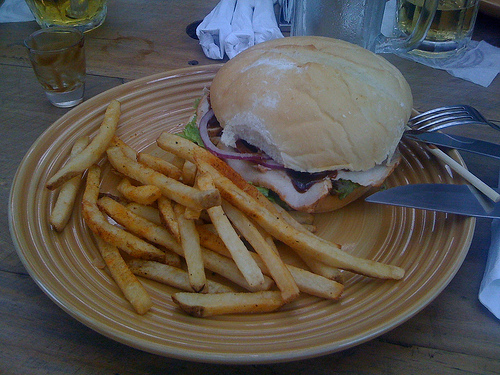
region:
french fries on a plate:
[35, 92, 422, 319]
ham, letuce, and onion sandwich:
[177, 26, 426, 223]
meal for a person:
[11, 28, 482, 362]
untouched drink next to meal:
[17, 21, 109, 113]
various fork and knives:
[354, 87, 497, 254]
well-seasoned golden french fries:
[41, 92, 438, 329]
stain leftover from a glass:
[93, 29, 162, 67]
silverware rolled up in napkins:
[175, 0, 323, 68]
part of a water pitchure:
[278, 3, 441, 71]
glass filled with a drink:
[22, 21, 99, 110]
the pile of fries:
[70, 140, 235, 285]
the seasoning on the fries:
[241, 205, 294, 235]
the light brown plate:
[24, 61, 478, 363]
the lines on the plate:
[303, 294, 355, 341]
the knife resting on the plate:
[363, 176, 497, 214]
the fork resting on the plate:
[411, 97, 498, 134]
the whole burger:
[199, 32, 406, 218]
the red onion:
[194, 107, 233, 165]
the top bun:
[223, 41, 380, 158]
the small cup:
[22, 27, 95, 107]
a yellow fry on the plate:
[41, 96, 126, 193]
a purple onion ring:
[194, 107, 264, 162]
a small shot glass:
[19, 19, 91, 112]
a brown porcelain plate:
[6, 62, 486, 367]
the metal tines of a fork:
[408, 102, 482, 135]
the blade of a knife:
[399, 127, 499, 164]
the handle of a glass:
[372, 0, 440, 55]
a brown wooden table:
[0, 0, 499, 373]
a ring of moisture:
[98, 29, 161, 67]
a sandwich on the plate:
[179, 32, 416, 217]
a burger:
[190, 26, 332, 253]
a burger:
[208, 94, 424, 247]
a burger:
[160, 9, 435, 267]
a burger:
[264, 66, 371, 224]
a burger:
[236, 36, 394, 179]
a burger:
[256, 60, 443, 339]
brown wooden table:
[6, 287, 70, 374]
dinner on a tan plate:
[28, 42, 480, 363]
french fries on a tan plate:
[39, 102, 227, 314]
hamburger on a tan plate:
[211, 37, 403, 218]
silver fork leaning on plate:
[410, 102, 492, 132]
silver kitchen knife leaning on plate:
[390, 125, 495, 161]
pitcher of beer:
[395, 2, 482, 66]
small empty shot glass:
[14, 27, 101, 112]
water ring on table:
[103, 25, 157, 68]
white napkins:
[192, 1, 292, 64]